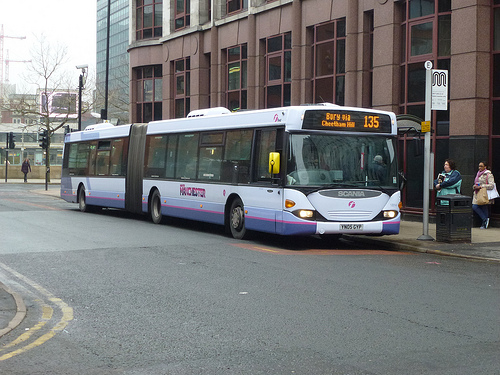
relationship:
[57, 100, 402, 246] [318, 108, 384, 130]
bus has readout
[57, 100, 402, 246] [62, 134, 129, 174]
bus has windows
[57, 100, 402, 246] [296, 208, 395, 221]
bus has headlights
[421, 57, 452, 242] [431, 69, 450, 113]
signpost has banner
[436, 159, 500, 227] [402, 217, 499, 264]
people are on sidewalk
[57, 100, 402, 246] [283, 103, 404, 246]
bus has front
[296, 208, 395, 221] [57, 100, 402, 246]
headlights are on bus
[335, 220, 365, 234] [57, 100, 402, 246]
license plate on bus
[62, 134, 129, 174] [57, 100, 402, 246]
windows are on bus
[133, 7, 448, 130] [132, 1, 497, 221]
windows are on building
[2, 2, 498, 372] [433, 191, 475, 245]
city has trash receptacle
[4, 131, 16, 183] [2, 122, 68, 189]
traffic light in distance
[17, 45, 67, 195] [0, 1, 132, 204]
tree in background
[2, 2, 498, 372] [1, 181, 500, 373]
city has street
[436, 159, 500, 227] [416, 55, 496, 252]
people at bus stop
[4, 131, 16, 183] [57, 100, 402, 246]
traffic light behind bus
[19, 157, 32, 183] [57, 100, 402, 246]
woman walking behind bus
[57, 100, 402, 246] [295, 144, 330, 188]
bus has driver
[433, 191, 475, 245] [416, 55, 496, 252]
trash receptacle at bus stop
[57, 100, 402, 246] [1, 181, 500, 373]
bus on street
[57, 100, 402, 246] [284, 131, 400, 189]
bus has windshield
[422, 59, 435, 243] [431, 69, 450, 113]
pole has sign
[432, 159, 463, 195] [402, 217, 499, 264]
person on sidewalk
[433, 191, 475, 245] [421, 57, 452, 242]
trash receptacle next to signpost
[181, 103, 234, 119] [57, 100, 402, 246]
vents are on bus